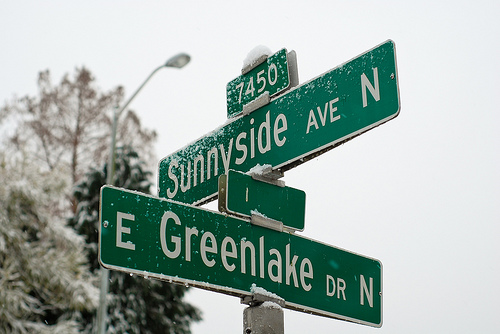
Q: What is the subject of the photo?
A: Street signs.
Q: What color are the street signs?
A: Green.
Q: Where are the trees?
A: Background.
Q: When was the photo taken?
A: Daytime.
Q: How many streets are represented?
A: Two.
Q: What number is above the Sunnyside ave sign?
A: 7450.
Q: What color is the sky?
A: White.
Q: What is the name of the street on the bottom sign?
A: E Greenlake dr.